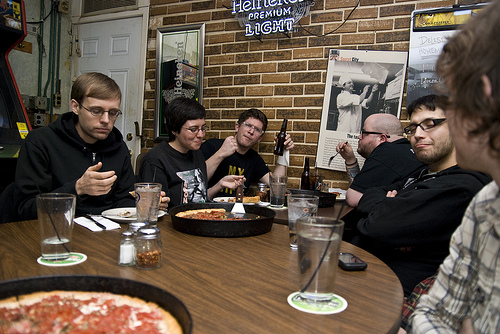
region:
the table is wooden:
[179, 134, 333, 329]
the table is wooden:
[147, 180, 268, 330]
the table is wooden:
[212, 235, 252, 310]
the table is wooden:
[171, 155, 252, 300]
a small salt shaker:
[115, 226, 135, 263]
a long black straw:
[27, 177, 73, 253]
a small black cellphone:
[335, 242, 365, 267]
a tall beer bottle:
[270, 112, 290, 152]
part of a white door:
[72, 15, 138, 165]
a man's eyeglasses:
[400, 115, 442, 130]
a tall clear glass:
[132, 181, 159, 224]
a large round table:
[1, 210, 404, 332]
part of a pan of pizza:
[0, 272, 193, 332]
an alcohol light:
[228, 0, 312, 37]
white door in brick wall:
[71, 20, 139, 189]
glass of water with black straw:
[40, 193, 73, 262]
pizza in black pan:
[7, 278, 157, 332]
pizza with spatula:
[171, 172, 278, 233]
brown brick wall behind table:
[152, 1, 497, 171]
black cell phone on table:
[338, 250, 363, 271]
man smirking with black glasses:
[405, 97, 452, 184]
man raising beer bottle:
[210, 113, 292, 188]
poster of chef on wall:
[326, 46, 401, 173]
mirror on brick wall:
[163, 34, 203, 154]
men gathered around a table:
[28, 6, 498, 332]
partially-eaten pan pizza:
[170, 199, 277, 238]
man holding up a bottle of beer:
[211, 101, 294, 200]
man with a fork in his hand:
[324, 104, 405, 209]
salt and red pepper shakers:
[115, 223, 175, 275]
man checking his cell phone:
[17, 69, 132, 212]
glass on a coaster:
[286, 197, 357, 315]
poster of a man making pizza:
[313, 41, 411, 173]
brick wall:
[203, 36, 321, 111]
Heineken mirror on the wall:
[153, 18, 208, 140]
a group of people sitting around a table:
[17, 19, 499, 331]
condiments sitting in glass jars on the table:
[113, 222, 161, 265]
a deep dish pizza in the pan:
[168, 195, 271, 235]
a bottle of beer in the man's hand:
[271, 117, 288, 154]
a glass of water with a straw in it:
[296, 210, 343, 303]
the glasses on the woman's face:
[173, 121, 209, 135]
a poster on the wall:
[318, 44, 406, 180]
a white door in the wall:
[73, 20, 145, 163]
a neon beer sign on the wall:
[221, 2, 312, 40]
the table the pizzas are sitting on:
[12, 208, 402, 332]